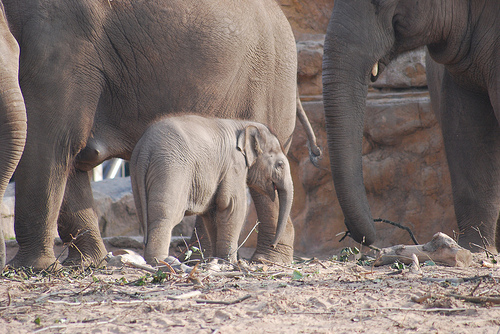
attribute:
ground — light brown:
[1, 237, 498, 333]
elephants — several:
[2, 2, 494, 245]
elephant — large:
[155, 130, 339, 277]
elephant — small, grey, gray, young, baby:
[127, 115, 294, 270]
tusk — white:
[366, 58, 382, 77]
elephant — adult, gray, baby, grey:
[320, 0, 499, 256]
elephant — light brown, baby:
[105, 70, 359, 278]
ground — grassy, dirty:
[42, 192, 497, 323]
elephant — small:
[138, 112, 340, 262]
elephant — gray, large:
[2, 2, 317, 272]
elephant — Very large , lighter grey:
[127, 108, 303, 276]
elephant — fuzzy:
[94, 117, 333, 273]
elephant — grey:
[120, 98, 323, 284]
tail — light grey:
[293, 91, 324, 163]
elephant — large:
[430, 53, 499, 254]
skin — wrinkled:
[114, 5, 281, 111]